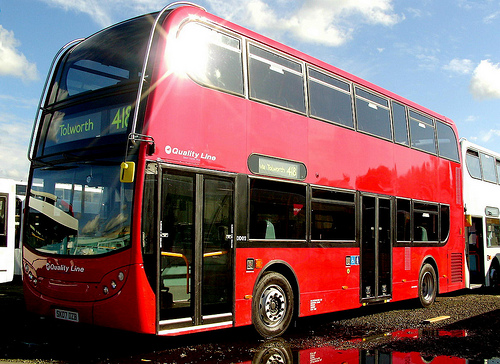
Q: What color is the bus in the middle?
A: Red.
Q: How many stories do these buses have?
A: Two.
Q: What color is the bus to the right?
A: White.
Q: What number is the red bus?
A: 418.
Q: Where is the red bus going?
A: Tolworth.